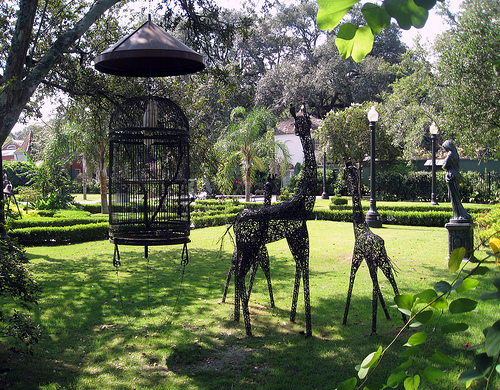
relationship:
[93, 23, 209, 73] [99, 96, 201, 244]
hood above birdcage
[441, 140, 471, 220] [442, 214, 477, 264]
statue on base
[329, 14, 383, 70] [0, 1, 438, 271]
leaf on tree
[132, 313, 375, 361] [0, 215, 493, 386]
shadows on ground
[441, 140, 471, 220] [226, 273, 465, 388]
statue on grass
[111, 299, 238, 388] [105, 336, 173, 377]
grass has worn patch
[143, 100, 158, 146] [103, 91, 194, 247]
bird in black cage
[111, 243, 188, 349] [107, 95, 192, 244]
chains under bird cage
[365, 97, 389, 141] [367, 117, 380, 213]
lamp on post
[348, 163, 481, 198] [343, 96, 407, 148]
hedge behind lamp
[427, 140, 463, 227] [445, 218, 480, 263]
statue on base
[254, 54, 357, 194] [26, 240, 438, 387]
trees provide shade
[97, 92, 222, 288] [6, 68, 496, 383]
bell in another courtyard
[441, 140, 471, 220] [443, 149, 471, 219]
statue wearing dress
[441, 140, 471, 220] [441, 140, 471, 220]
statue depicting statue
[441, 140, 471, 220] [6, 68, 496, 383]
statue standing in courtyard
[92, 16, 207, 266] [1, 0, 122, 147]
birdcage hanging from tree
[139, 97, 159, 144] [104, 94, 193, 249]
bird sitting inside birdcage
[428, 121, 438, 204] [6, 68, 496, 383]
street lamp standing in courtyard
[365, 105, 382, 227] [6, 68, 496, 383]
street lamp standing in courtyard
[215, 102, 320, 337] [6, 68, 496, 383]
iron giraffe standing in courtyard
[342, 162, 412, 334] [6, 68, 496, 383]
iron giraffe standing in courtyard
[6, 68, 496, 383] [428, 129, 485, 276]
courtyard has a statue